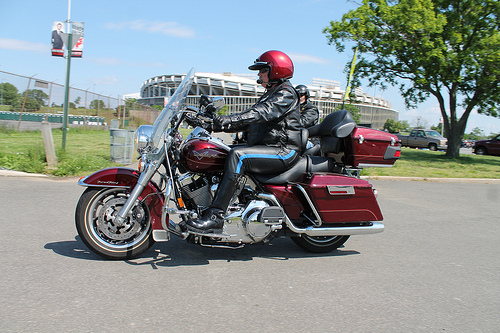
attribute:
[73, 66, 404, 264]
motorcycle — maroon, driving, red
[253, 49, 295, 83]
helmet — red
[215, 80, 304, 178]
leather — black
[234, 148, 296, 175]
stripe — blue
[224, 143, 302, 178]
pants — leather, black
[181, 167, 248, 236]
boot — black, leather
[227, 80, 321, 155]
jackets — leather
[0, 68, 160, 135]
fence — chainlink, tall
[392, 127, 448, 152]
truck — tan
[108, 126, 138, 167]
can — silver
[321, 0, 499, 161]
tree — large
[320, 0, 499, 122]
leaves — green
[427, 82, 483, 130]
branches — brown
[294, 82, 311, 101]
helmet — black